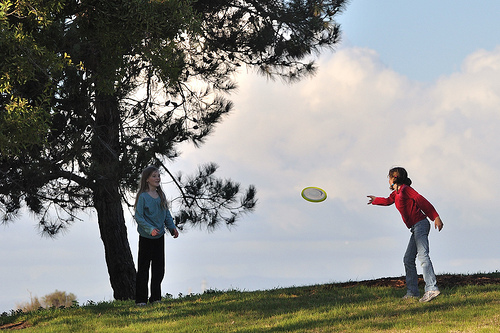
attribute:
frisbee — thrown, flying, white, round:
[300, 187, 327, 203]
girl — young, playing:
[366, 166, 446, 304]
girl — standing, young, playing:
[134, 166, 180, 304]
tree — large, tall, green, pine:
[1, 0, 350, 300]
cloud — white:
[132, 2, 420, 200]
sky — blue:
[1, 0, 499, 313]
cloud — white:
[403, 46, 500, 222]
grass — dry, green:
[1, 269, 500, 332]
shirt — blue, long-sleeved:
[134, 190, 176, 237]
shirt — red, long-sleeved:
[372, 184, 440, 228]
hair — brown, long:
[390, 166, 412, 187]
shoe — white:
[419, 290, 441, 301]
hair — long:
[134, 166, 169, 210]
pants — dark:
[134, 234, 165, 306]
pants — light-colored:
[403, 216, 439, 295]